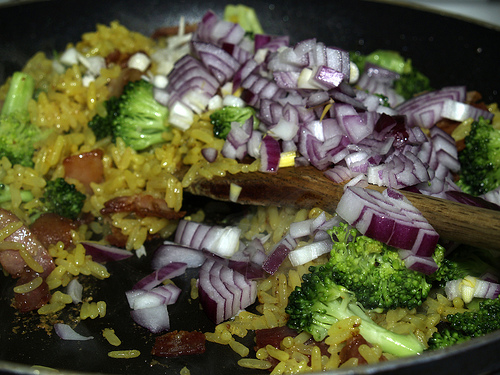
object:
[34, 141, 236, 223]
tomatoes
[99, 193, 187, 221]
meat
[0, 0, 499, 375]
frying pan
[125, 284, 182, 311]
onion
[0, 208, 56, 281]
sausage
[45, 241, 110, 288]
rice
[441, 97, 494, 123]
onion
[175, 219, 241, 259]
onion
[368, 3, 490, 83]
wok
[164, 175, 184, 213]
rice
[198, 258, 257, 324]
onion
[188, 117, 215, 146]
rice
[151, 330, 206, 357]
bacon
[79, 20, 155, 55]
rice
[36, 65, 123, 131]
rice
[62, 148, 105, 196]
pepper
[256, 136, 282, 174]
onions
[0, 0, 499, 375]
skillet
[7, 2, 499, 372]
wok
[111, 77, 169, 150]
broccoli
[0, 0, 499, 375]
pan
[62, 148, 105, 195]
bacon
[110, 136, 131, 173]
rice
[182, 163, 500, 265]
spoon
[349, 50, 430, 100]
broccoli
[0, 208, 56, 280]
pepper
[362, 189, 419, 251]
onion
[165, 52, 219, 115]
onion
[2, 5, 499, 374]
dish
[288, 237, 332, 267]
onion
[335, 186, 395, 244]
onion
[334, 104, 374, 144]
onion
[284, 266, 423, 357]
broccoli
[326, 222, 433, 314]
broccoli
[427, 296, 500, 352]
broccoli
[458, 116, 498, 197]
broccoli